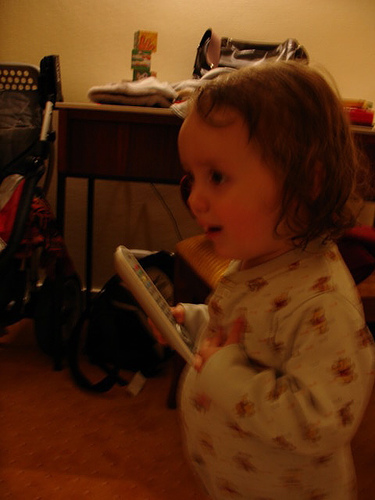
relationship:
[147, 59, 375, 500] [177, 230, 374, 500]
baby wearing clothing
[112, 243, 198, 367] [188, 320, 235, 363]
controller in hand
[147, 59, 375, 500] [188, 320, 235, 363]
baby has hand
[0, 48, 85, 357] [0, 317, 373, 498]
stroller sitting on floor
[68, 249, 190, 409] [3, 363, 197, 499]
bag sitting on floor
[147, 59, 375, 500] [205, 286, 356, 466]
baby wearing clothing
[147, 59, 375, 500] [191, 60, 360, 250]
baby has hair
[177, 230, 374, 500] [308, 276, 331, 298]
clothing has design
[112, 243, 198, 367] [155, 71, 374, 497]
controller in child's hand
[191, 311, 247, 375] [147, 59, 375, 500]
child's hand on baby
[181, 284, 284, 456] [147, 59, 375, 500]
chest on baby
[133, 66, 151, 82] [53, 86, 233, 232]
block on table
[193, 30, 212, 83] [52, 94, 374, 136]
strap on table top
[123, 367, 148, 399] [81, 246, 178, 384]
tag on bag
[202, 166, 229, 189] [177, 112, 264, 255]
eye on face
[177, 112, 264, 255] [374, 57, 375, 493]
face on child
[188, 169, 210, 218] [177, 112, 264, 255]
nose on face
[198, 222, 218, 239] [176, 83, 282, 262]
mouth on face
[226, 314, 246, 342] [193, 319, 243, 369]
thumb on hand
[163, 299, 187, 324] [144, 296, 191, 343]
thumb on hand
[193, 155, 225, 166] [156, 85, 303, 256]
eyebrow on face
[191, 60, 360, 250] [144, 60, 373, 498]
hair on baby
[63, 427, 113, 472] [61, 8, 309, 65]
ground in house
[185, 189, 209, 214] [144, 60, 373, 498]
nose on baby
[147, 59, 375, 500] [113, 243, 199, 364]
baby holding controller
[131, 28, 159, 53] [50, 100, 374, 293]
block on table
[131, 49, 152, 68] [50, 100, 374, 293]
block on table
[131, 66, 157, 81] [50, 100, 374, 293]
block on table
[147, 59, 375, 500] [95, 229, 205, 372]
baby holding controller